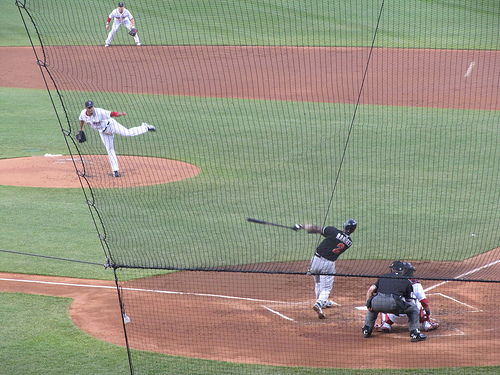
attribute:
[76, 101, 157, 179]
pitcher — releasing, throwing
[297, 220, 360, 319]
player — swinging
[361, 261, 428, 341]
umpire — crouching, watching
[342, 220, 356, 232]
helmet — black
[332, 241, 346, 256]
number — red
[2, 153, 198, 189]
pitcher's mound — round, dirt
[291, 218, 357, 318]
batter — swinging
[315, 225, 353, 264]
jersey — black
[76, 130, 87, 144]
glove — black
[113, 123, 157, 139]
left leg — lifted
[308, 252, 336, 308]
pants — white, gray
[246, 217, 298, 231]
bat — long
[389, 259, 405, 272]
hat — black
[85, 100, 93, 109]
hat — blue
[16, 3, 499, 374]
net — in front, blue, large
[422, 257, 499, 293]
line — white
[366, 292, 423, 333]
pants — gray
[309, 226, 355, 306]
uniform — black, white